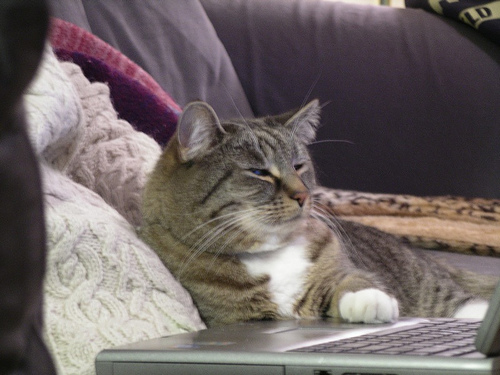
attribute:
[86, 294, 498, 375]
laptop — small, silver, silvery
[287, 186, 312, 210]
nose — pink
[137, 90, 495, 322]
cat — glaring, small, doing, resting, tabby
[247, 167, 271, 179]
eye — half closed, dark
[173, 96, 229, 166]
ear — white, gray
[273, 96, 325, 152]
ear — white, gray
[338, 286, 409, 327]
paw — white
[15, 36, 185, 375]
afghan — white, crochet, knit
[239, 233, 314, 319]
fur — white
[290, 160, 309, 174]
eye — half closed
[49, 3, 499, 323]
couch — gray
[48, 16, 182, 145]
blanket — red, purple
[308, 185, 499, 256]
blanket — leopard printed, brown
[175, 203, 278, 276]
whiskers — long, white